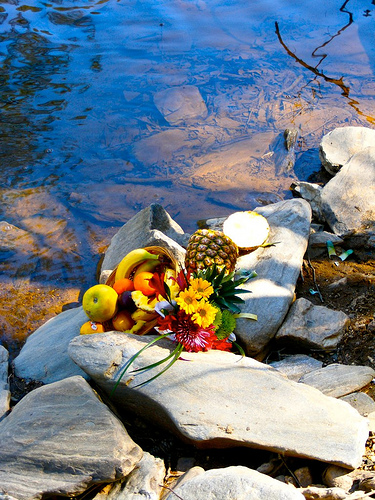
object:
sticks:
[226, 73, 295, 143]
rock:
[152, 84, 209, 126]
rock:
[198, 197, 313, 354]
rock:
[130, 128, 198, 168]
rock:
[178, 130, 288, 210]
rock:
[318, 124, 375, 175]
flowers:
[157, 314, 174, 331]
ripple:
[3, 2, 187, 194]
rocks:
[64, 330, 371, 471]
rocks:
[0, 373, 146, 499]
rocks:
[291, 106, 351, 149]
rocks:
[0, 180, 62, 256]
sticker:
[90, 320, 97, 330]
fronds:
[213, 265, 228, 290]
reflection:
[305, 17, 354, 77]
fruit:
[79, 209, 269, 347]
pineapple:
[184, 228, 239, 293]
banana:
[115, 248, 163, 284]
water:
[0, 0, 375, 352]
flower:
[191, 301, 219, 328]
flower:
[173, 312, 215, 351]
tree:
[0, 0, 79, 183]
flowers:
[144, 271, 169, 304]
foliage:
[108, 332, 182, 401]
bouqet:
[189, 271, 233, 304]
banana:
[132, 259, 163, 282]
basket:
[103, 244, 183, 336]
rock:
[165, 462, 311, 498]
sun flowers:
[169, 281, 180, 301]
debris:
[327, 240, 336, 259]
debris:
[338, 249, 353, 262]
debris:
[334, 261, 340, 266]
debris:
[309, 288, 320, 295]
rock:
[7, 304, 86, 386]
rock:
[293, 135, 375, 237]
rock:
[275, 297, 349, 356]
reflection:
[1, 0, 105, 186]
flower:
[184, 296, 220, 330]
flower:
[174, 288, 202, 314]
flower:
[189, 277, 214, 300]